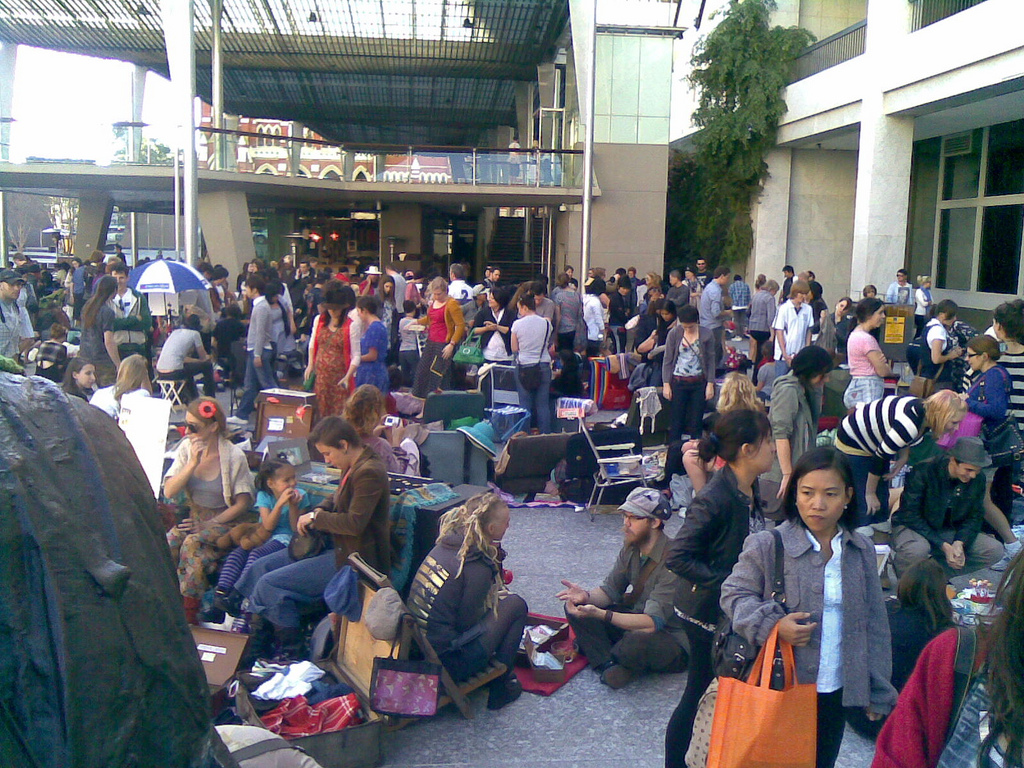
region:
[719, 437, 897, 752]
The lay with the orange shopping bag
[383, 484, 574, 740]
the person on the floor with blonde hair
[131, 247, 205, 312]
The white and blue umbrella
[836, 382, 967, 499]
the lady bending down with the black and white stripped shirt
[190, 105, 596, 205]
the upper level railing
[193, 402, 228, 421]
the flower in the girls hair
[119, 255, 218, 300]
blue and white umbrealla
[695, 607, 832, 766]
orange fabric shopping bag over a woman's arm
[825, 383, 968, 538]
blond girl is leaning over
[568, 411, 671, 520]
an empty folding picnic chair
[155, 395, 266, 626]
woman has a red flower in her hair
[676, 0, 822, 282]
green plant growing on a building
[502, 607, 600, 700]
small red blanket on the floor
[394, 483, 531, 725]
woman is sitting on a small folding wooden chair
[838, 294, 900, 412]
woman wears a pink shirt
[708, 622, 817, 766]
the bag is orange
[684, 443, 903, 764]
the woman is carrying the orange bag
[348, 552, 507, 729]
the chair is foldable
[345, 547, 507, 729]
the chair is brown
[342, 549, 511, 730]
the chair is made of wood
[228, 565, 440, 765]
the luggage is filled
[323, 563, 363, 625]
the hat is blue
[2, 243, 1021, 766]
the large group of people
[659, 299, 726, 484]
A person is standing up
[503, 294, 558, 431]
A person is standing up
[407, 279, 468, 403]
A person is standing up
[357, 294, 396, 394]
A person is standing up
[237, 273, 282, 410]
A person is standing up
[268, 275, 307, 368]
A person is standing up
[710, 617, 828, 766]
woman holding orange shopping bag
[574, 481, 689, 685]
man sitting on floor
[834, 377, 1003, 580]
woman leaning over man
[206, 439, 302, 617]
girl wearing a blue shirt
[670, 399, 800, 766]
woman wearing pony tail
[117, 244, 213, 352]
umbrella is blue and white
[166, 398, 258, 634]
woman has orange flower in hair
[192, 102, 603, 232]
balcony on side of building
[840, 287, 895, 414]
woman wearing pink shirt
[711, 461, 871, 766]
a woman carrying an orange bag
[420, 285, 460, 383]
a person in a red shirt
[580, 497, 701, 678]
a man sitting on the ground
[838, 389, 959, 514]
a woman in a striped shirt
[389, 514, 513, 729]
a woman sitting on a chair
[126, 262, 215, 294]
a white and blue umbrella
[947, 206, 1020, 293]
windows on the building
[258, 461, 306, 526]
a child in a blue shirt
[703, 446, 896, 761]
woman with an orange tote bag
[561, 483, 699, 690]
man sitting on the ground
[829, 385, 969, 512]
woman in a black and white striped sweater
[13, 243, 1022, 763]
crowd of people gathered together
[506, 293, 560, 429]
woman with a purse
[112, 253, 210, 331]
blue and white umbrella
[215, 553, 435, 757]
open suitcase of clothing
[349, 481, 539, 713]
person sitting on a chair